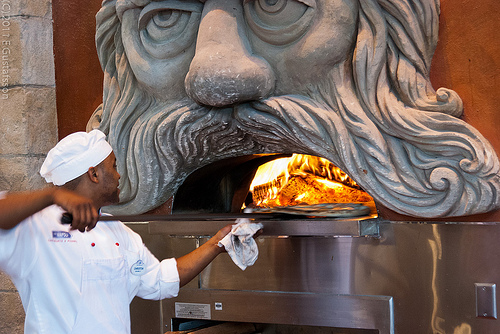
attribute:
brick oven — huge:
[84, 2, 498, 222]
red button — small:
[88, 242, 100, 247]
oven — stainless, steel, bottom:
[98, 207, 499, 332]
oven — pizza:
[146, 122, 444, 324]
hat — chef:
[30, 120, 130, 179]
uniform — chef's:
[26, 215, 106, 321]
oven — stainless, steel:
[121, 221, 495, 332]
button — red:
[91, 240, 96, 248]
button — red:
[113, 242, 122, 246]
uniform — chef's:
[3, 213, 176, 333]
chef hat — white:
[37, 119, 117, 189]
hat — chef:
[39, 127, 115, 191]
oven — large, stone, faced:
[78, 1, 498, 271]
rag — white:
[216, 207, 263, 271]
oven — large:
[98, 140, 497, 332]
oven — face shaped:
[56, 3, 498, 223]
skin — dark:
[92, 170, 116, 198]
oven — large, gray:
[93, 98, 460, 321]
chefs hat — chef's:
[35, 130, 115, 189]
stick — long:
[201, 191, 374, 231]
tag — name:
[124, 251, 151, 281]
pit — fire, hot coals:
[172, 144, 382, 215]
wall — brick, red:
[54, 1, 484, 221]